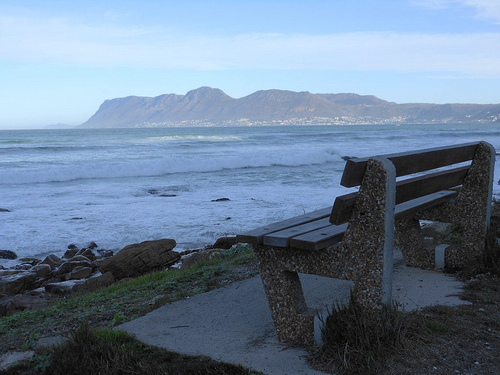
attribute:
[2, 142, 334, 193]
water — agitated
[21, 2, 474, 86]
blue sky — light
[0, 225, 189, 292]
clump — rocks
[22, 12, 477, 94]
sky — cloudy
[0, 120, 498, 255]
water — large, body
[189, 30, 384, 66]
cloud — thin, long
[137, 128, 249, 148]
wave — small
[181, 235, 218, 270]
clump — grass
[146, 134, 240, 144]
cap — white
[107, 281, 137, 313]
grass — small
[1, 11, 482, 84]
clouds — white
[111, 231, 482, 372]
concete — slab